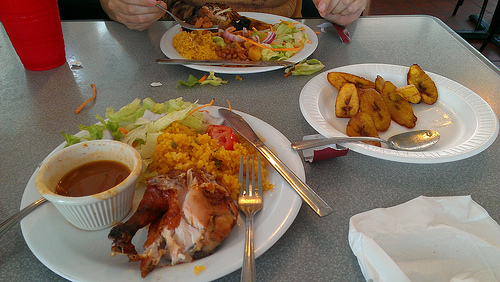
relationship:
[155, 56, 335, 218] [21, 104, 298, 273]
knives balancing on a plate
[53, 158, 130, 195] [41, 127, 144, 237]
gravy inside bowl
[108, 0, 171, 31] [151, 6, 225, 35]
hand holding fork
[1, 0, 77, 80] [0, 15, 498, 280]
cup on table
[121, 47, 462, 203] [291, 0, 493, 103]
plantains on plate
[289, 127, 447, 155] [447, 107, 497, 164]
spoon on plate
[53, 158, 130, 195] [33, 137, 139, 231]
gravy in cup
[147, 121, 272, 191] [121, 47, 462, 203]
rice near plantains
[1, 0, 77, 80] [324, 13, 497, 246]
cup on table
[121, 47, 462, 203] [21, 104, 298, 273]
plantains on plate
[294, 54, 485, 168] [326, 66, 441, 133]
plate with plantains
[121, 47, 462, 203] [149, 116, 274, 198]
plantains with rice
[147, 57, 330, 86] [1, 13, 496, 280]
lettuce on table top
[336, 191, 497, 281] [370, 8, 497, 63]
paper on table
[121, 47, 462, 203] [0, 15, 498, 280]
plantains on table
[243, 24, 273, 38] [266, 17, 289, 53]
onion on lettuce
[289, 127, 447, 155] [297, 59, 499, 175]
spoon on plate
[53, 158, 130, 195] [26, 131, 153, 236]
gravy on bowl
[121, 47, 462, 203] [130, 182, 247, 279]
plantains next chicken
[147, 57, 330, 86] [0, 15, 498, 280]
lettuce on table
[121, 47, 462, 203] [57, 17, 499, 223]
plantains on plate